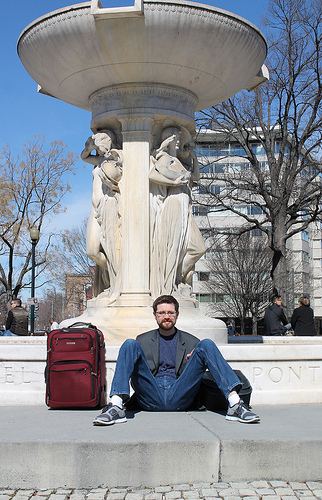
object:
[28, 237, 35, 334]
pole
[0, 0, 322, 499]
spectacle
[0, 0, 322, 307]
sky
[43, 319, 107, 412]
luggage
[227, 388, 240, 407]
sock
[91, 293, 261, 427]
man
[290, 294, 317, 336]
woman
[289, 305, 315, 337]
coat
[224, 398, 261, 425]
shoe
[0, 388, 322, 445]
floor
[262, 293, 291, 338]
man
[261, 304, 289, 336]
suit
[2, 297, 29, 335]
man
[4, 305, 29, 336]
vest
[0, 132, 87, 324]
tree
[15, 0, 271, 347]
monument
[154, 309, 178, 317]
glasses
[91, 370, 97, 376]
zipper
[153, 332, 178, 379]
shirt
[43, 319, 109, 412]
luggage bag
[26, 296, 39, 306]
sign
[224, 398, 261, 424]
left foot